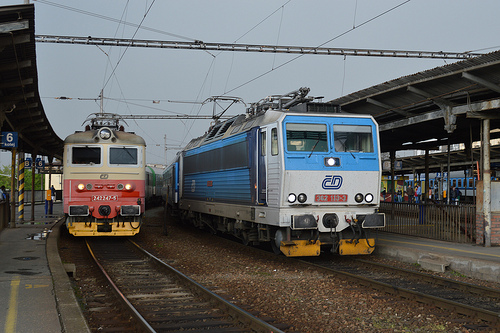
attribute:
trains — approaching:
[83, 98, 377, 245]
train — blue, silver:
[181, 98, 461, 321]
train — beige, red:
[62, 120, 149, 240]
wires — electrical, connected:
[56, 14, 344, 116]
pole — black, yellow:
[0, 153, 60, 218]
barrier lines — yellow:
[6, 275, 44, 325]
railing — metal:
[364, 156, 491, 251]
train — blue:
[191, 114, 376, 239]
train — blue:
[170, 122, 396, 262]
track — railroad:
[75, 249, 254, 327]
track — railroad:
[319, 251, 499, 318]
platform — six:
[0, 123, 84, 283]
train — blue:
[195, 118, 361, 237]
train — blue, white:
[166, 118, 403, 270]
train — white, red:
[31, 115, 137, 239]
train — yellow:
[70, 220, 166, 271]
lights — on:
[278, 129, 381, 251]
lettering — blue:
[320, 172, 346, 191]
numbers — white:
[84, 185, 125, 205]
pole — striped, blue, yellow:
[12, 145, 32, 226]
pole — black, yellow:
[12, 145, 28, 223]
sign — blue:
[4, 124, 16, 147]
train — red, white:
[59, 109, 149, 250]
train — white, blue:
[159, 94, 379, 264]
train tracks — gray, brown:
[81, 229, 268, 330]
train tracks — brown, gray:
[77, 236, 284, 330]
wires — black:
[35, 4, 498, 98]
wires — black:
[35, 22, 498, 67]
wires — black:
[55, 94, 251, 124]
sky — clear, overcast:
[28, 7, 497, 163]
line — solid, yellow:
[1, 280, 24, 325]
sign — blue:
[1, 125, 31, 154]